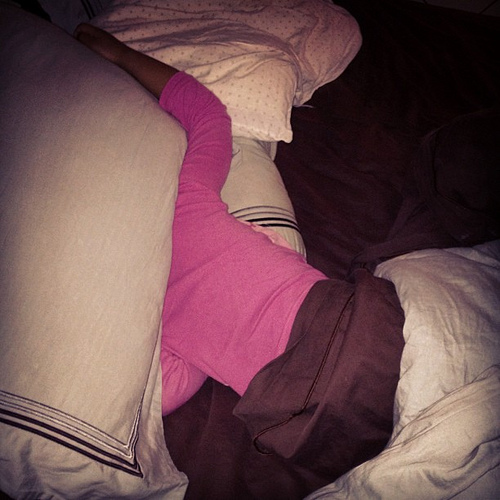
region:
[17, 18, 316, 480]
a person is sleeping under a pillow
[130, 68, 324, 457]
the person has a pink blouse on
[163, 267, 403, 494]
a blanket is folded around the person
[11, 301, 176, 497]
the pillow has a black trim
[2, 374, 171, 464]
the pillow has a white trim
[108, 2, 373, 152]
this pillow has a dot design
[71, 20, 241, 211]
the arm of the person is above the pillow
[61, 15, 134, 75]
the hand is closed next to the pillow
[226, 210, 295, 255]
light pink material is in front of the person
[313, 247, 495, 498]
a white coverlet is on the bed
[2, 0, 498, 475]
a girl sleeping in a bed.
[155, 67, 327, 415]
a girl in a pink shirt.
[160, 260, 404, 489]
a brown blanket on a girl.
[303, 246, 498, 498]
a white blanket over a girl.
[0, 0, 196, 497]
a large pillow on a bed.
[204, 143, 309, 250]
a pillow under a girl.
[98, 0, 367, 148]
a dotted pillow on a bed.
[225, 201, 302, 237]
lines on a pillow.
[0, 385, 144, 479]
lines on the side of a pillow.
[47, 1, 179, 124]
a arm on a pillow.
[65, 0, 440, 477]
Person with a pink shirt on.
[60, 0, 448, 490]
Person lying in bed.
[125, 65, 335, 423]
Pink shirt on the person.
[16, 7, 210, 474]
Person's head is under the pillow.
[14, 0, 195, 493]
Pillow over person's head.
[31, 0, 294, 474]
Three pillows on the bed.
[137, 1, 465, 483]
The sheets are brown.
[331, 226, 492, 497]
Blanket is white.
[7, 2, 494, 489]
One person in the bed.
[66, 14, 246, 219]
Person's right arm sticking out.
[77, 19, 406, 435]
The person in the pink shirt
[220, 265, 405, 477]
The brown sheet wrapped around the person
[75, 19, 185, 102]
The exposed skin of the person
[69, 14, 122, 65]
The person's right hand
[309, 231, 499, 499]
The white comforter over the person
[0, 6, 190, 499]
The pillow on the person's head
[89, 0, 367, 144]
The white pillow with dots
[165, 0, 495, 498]
The brown sheet under the person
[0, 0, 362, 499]
The pillows on the bed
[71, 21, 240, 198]
The right arm of the person in pink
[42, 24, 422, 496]
person in pink shirt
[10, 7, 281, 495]
person's head under white pillow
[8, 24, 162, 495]
pillow with black and silver embellishment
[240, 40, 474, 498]
brown sheet on bed in photo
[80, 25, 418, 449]
person sleeping under pillow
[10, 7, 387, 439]
several pillows on bed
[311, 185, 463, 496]
person wrapped in brown sheet and white blanket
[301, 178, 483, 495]
white comforter on bed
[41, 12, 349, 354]
one hand on person visilbe in photograph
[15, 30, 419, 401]
one pillow over persons head